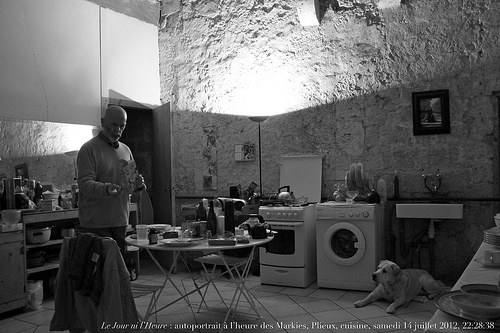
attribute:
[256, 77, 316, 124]
wall — REAR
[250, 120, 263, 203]
pedestal lamp — illuminated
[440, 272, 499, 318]
plate — small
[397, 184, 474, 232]
sink — white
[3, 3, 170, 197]
wall — white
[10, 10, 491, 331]
photo — black and white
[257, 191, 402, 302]
machines — WASHING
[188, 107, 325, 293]
cooker — open